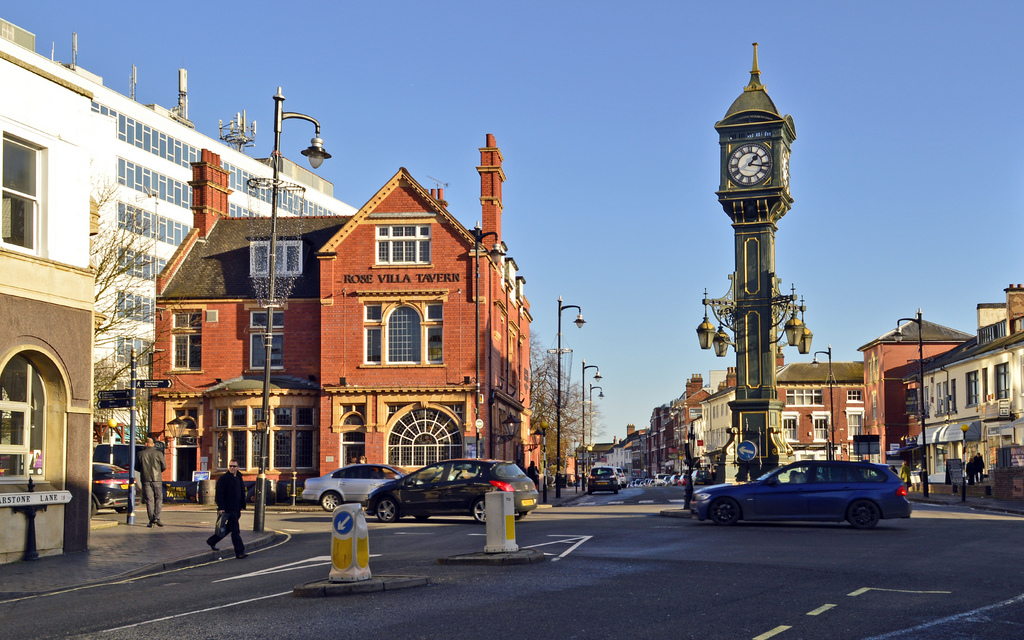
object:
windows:
[376, 388, 472, 472]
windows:
[209, 389, 322, 472]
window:
[170, 308, 203, 372]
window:
[248, 239, 304, 279]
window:
[375, 223, 434, 267]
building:
[315, 129, 542, 486]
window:
[362, 324, 382, 367]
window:
[423, 322, 444, 364]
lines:
[807, 601, 838, 615]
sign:
[331, 510, 358, 537]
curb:
[327, 502, 375, 583]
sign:
[0, 488, 77, 510]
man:
[205, 457, 250, 559]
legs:
[205, 510, 250, 559]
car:
[689, 459, 914, 531]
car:
[364, 457, 541, 524]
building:
[144, 129, 547, 499]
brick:
[454, 314, 465, 330]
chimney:
[185, 148, 236, 237]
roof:
[153, 214, 357, 301]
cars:
[300, 462, 407, 512]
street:
[91, 501, 1024, 640]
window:
[169, 221, 532, 483]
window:
[353, 288, 449, 371]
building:
[0, 18, 364, 525]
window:
[0, 122, 52, 263]